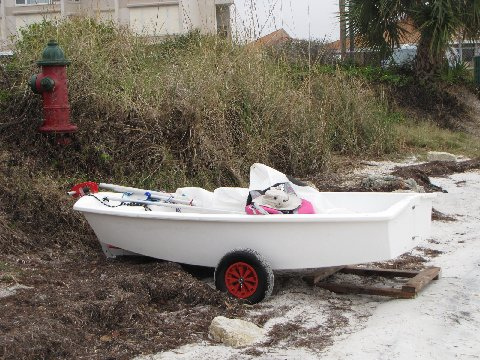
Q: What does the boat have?
A: Wheels.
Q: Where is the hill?
A: Behind the boat.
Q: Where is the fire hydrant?
A: On the hill.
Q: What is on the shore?
A: It's a small white boat.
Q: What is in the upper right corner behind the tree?
A: A white house on the beach.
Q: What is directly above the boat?
A: A small slope covered in weeds and grass.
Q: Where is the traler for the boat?
A: It is laying in the sand.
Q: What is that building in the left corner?
A: Its a large cement building.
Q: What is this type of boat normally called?
A: Its called a dingy.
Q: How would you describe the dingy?
A: Its white and has red wheels.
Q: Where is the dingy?
A: Its on a beach.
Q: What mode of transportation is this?
A: White boat.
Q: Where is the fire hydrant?
A: In mound of dirt above boat.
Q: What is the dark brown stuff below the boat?
A: Dried seaweed.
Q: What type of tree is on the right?
A: Palm tree.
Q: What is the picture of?
A: A boat on a trailer on the riverbank.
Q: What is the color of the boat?
A: White.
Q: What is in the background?
A: A house and some dry bushes.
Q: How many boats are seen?
A: One.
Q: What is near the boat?
A: A firehydrant.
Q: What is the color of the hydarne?
A: Red and green top.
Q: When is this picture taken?
A: Daytime.